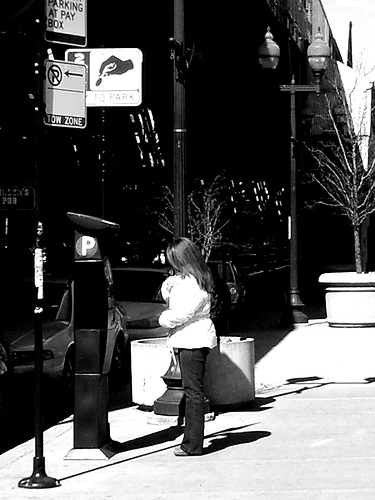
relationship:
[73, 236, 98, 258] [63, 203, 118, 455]
writing on machine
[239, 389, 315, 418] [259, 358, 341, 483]
shadow on ground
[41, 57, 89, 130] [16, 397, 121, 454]
sign above road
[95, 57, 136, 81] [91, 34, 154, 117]
design on sign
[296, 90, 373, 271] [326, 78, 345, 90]
tree has no leaves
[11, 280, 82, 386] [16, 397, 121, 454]
car on road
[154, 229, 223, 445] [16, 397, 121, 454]
woman beside road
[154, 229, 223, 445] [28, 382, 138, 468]
female on street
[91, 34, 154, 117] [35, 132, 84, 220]
sign on pole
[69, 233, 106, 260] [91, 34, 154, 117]
p on sign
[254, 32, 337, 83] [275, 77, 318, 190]
lights on pole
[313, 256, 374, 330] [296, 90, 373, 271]
pot holds tree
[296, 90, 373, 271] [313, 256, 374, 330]
tree in pot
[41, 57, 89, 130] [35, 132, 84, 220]
sign on pole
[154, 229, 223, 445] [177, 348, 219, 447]
woman wears pants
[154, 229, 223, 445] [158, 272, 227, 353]
woman wears jacket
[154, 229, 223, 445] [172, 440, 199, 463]
woman wears shoes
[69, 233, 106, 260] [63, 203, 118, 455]
p on meter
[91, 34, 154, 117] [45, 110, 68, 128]
sign for towing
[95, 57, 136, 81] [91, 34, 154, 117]
hand on sign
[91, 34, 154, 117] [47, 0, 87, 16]
sign for parking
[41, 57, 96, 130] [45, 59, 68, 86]
sign for no parking